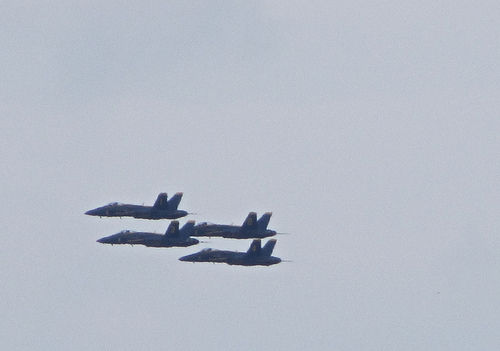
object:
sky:
[0, 0, 498, 349]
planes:
[177, 236, 285, 265]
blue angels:
[96, 219, 200, 248]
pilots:
[82, 191, 192, 221]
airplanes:
[86, 188, 190, 220]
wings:
[153, 191, 170, 209]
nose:
[80, 203, 103, 219]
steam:
[276, 228, 296, 233]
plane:
[187, 212, 277, 239]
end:
[173, 195, 189, 219]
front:
[96, 235, 109, 243]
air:
[283, 0, 500, 350]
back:
[178, 207, 194, 227]